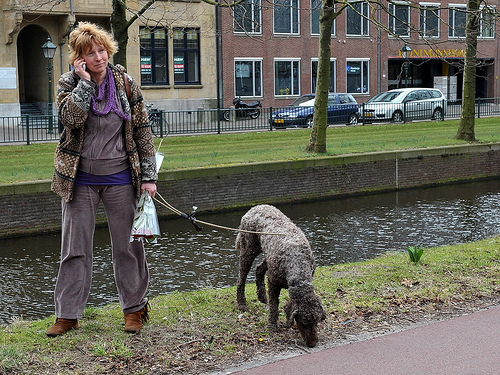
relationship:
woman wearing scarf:
[46, 20, 156, 334] [86, 66, 128, 125]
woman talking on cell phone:
[46, 20, 156, 334] [77, 60, 88, 69]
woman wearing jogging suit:
[46, 20, 156, 334] [45, 61, 160, 201]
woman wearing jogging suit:
[46, 20, 156, 334] [53, 69, 149, 320]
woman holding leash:
[46, 20, 156, 334] [145, 191, 295, 238]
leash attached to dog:
[145, 191, 295, 238] [234, 204, 327, 348]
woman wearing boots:
[46, 20, 156, 334] [44, 301, 152, 335]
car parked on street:
[271, 93, 360, 128] [159, 97, 499, 136]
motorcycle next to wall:
[222, 96, 261, 120] [221, 2, 392, 121]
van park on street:
[358, 87, 446, 119] [159, 97, 499, 136]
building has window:
[2, 1, 220, 132] [173, 29, 203, 83]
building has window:
[2, 1, 220, 132] [139, 28, 167, 83]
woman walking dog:
[46, 20, 156, 334] [234, 204, 327, 348]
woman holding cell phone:
[46, 20, 156, 334] [77, 60, 88, 69]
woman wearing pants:
[46, 20, 156, 334] [50, 182, 149, 316]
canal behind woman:
[0, 176, 499, 326] [46, 20, 156, 334]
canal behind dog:
[0, 176, 499, 326] [234, 204, 327, 348]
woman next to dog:
[46, 20, 156, 334] [234, 204, 327, 348]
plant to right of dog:
[406, 242, 424, 259] [234, 204, 327, 348]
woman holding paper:
[46, 20, 156, 334] [130, 151, 164, 244]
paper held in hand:
[130, 151, 164, 244] [140, 181, 156, 198]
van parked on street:
[358, 87, 446, 119] [159, 97, 499, 136]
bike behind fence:
[146, 104, 167, 131] [1, 101, 499, 146]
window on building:
[173, 29, 203, 83] [2, 1, 220, 132]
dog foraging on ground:
[234, 204, 327, 348] [3, 235, 499, 372]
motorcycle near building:
[222, 96, 261, 120] [219, 1, 500, 117]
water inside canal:
[1, 177, 499, 326] [0, 176, 499, 326]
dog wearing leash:
[234, 204, 327, 348] [145, 191, 295, 238]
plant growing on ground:
[406, 242, 424, 259] [3, 235, 499, 372]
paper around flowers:
[130, 151, 164, 244] [134, 232, 156, 241]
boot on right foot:
[46, 316, 80, 338] [46, 318, 79, 338]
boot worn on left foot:
[123, 301, 152, 333] [122, 318, 146, 332]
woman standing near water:
[46, 20, 156, 334] [1, 177, 499, 326]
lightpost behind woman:
[40, 37, 58, 134] [46, 20, 156, 334]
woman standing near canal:
[46, 20, 156, 334] [0, 176, 499, 326]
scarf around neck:
[86, 66, 128, 125] [88, 70, 108, 84]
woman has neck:
[46, 20, 156, 334] [88, 70, 108, 84]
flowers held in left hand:
[134, 232, 156, 241] [140, 181, 156, 198]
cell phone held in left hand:
[77, 60, 88, 69] [72, 59, 91, 82]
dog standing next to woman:
[234, 204, 327, 348] [46, 20, 156, 334]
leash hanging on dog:
[145, 191, 295, 238] [234, 204, 327, 348]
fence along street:
[1, 101, 499, 146] [159, 97, 499, 136]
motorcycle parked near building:
[222, 96, 261, 120] [219, 1, 500, 117]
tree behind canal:
[306, 3, 414, 153] [0, 176, 499, 326]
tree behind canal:
[415, 0, 500, 141] [0, 176, 499, 326]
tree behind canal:
[1, 0, 246, 74] [0, 176, 499, 326]